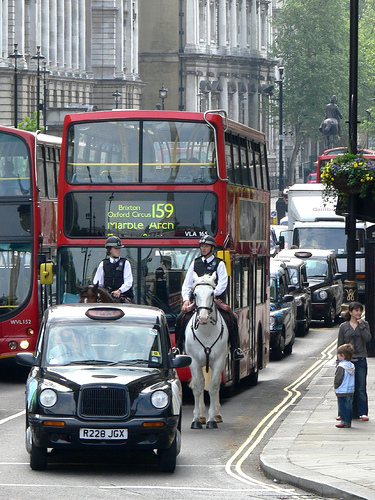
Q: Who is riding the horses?
A: Officers.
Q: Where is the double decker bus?
A: On road.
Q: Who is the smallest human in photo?
A: Little boy.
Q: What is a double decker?
A: The bus.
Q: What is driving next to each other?
A: Two buses.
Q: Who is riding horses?
A: Two people.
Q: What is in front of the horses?
A: A small compact car.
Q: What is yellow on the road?
A: Lines.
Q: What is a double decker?
A: The red bus.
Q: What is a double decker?
A: The red bus.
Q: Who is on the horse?
A: A police officer.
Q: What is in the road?
A: Bus.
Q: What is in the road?
A: Double decker bus.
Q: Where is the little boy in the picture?
A: On the sidewalk.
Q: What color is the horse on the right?
A: White.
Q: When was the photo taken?
A: Daytime.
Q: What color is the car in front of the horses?
A: Black.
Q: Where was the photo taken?
A: In the city.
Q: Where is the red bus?
A: Behind the horses.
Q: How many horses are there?
A: Two.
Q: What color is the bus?
A: Red.